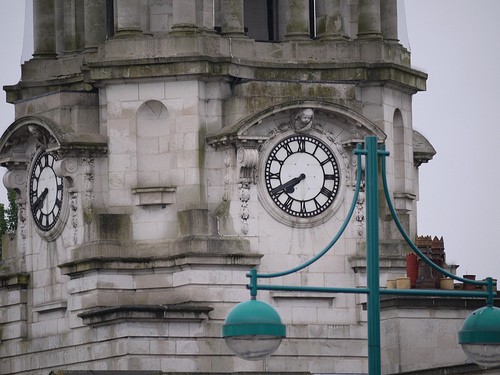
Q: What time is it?
A: 7:40.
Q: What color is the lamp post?
A: Green.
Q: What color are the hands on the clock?
A: Black.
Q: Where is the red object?
A: On the right.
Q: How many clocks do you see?
A: Two.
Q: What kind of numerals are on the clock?
A: Roman.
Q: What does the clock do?
A: Tell time.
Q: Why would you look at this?
A: To tell time.